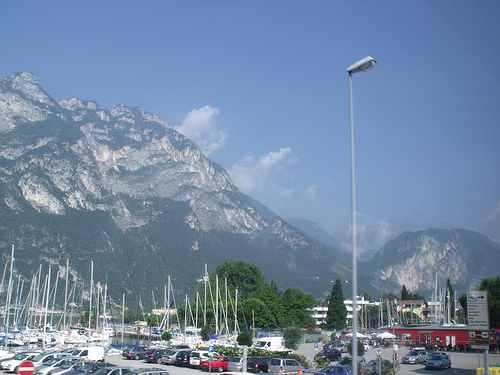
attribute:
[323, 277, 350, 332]
tree — green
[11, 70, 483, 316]
mountain — big, snow capped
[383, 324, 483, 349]
building — long, red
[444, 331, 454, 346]
doors — white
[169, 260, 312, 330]
trees — green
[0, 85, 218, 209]
mountains — snowy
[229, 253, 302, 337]
trees — green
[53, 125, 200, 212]
snow — white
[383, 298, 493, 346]
building — red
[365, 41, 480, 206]
sky — blue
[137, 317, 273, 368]
cars — parked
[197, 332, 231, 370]
car — red, compact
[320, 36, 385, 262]
streetlight — tall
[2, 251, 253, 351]
sailboats — parked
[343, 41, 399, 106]
light — off